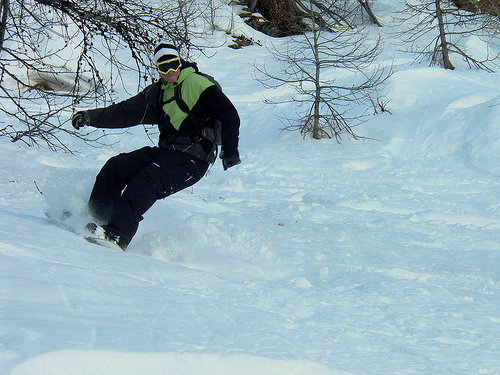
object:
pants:
[86, 142, 220, 248]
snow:
[0, 0, 499, 371]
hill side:
[0, 0, 499, 371]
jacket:
[83, 60, 243, 164]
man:
[70, 44, 241, 251]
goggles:
[156, 57, 182, 74]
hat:
[153, 43, 178, 63]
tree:
[385, 0, 498, 75]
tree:
[249, 0, 401, 146]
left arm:
[211, 89, 240, 168]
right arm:
[44, 43, 243, 251]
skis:
[44, 206, 123, 252]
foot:
[86, 223, 126, 251]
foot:
[64, 209, 77, 221]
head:
[155, 43, 181, 83]